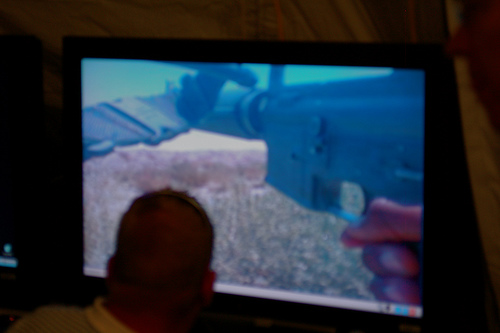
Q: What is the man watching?
A: A TV.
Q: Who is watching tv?
A: A man.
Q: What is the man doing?
A: Watching the tv.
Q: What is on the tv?
A: Gun.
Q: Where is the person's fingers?
A: Under the gun's trigger.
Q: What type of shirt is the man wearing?
A: Collar.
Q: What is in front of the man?
A: Tv.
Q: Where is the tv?
A: Inside a room.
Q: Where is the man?
A: Inside a room.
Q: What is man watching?
A: A video game.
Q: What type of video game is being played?
A: Shooting game.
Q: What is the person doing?
A: Watching television.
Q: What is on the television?
A: A firearm.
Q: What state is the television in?
A: On.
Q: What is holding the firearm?
A: A hand.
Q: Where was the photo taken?
A: In a room.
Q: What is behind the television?
A: A wall.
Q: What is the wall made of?
A: Wood.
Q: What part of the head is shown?
A: The back.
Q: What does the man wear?
A: A shirt.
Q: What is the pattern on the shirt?
A: Stripes.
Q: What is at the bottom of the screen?
A: Grey bar at the bottom of the computer screen.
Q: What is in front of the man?
A: A computer monitor in front of a man.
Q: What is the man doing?
A: A man looking at a monitor.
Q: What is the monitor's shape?
A: The monitor has a rectangular shape.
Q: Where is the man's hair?
A: The man has no hair.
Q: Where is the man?
A: A man by a computer monitor.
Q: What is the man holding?
A: The handle of gun.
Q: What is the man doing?
A: A man watching tv.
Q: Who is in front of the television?
A: A man.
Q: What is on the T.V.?
A: A show.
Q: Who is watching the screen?
A: The man.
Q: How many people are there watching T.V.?
A: One.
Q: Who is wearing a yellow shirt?
A: The man.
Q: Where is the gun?
A: On T.V.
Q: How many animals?
A: None.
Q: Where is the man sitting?
A: In front of T.V.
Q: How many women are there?
A: None.